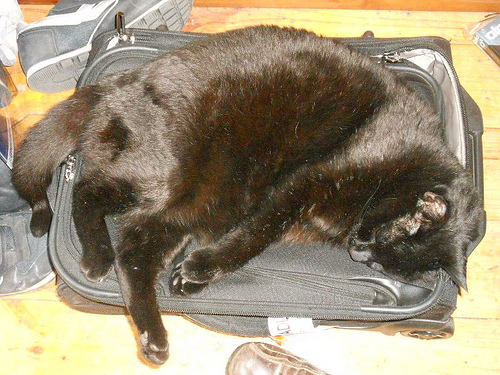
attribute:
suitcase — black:
[55, 20, 459, 320]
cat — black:
[50, 26, 458, 337]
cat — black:
[79, 57, 452, 319]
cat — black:
[80, 28, 470, 335]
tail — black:
[19, 77, 109, 236]